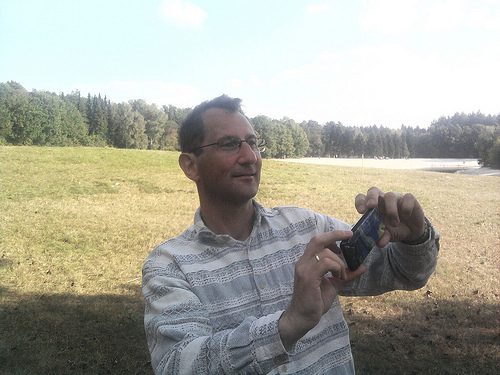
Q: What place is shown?
A: It is a field.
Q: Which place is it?
A: It is a field.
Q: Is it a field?
A: Yes, it is a field.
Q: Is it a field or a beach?
A: It is a field.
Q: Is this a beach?
A: No, it is a field.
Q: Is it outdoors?
A: Yes, it is outdoors.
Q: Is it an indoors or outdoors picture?
A: It is outdoors.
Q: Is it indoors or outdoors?
A: It is outdoors.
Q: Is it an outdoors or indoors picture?
A: It is outdoors.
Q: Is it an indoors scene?
A: No, it is outdoors.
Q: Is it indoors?
A: No, it is outdoors.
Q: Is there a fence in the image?
A: No, there are no fences.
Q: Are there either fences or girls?
A: No, there are no fences or girls.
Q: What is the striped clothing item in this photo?
A: The clothing item is a shirt.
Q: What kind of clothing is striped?
A: The clothing is a shirt.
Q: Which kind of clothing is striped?
A: The clothing is a shirt.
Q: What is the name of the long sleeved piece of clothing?
A: The clothing item is a shirt.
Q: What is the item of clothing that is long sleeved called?
A: The clothing item is a shirt.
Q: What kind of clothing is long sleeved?
A: The clothing is a shirt.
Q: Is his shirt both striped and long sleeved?
A: Yes, the shirt is striped and long sleeved.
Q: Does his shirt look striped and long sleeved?
A: Yes, the shirt is striped and long sleeved.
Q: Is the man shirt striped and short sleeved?
A: No, the shirt is striped but long sleeved.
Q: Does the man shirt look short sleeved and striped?
A: No, the shirt is striped but long sleeved.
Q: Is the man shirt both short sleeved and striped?
A: No, the shirt is striped but long sleeved.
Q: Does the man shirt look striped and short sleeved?
A: No, the shirt is striped but long sleeved.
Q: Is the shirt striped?
A: Yes, the shirt is striped.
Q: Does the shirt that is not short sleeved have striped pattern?
A: Yes, the shirt is striped.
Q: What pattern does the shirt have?
A: The shirt has striped pattern.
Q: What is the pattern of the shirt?
A: The shirt is striped.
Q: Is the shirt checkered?
A: No, the shirt is striped.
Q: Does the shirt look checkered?
A: No, the shirt is striped.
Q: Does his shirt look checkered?
A: No, the shirt is striped.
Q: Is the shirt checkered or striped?
A: The shirt is striped.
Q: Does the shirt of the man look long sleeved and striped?
A: Yes, the shirt is long sleeved and striped.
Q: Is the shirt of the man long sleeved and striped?
A: Yes, the shirt is long sleeved and striped.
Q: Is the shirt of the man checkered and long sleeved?
A: No, the shirt is long sleeved but striped.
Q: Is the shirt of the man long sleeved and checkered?
A: No, the shirt is long sleeved but striped.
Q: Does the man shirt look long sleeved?
A: Yes, the shirt is long sleeved.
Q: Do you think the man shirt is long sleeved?
A: Yes, the shirt is long sleeved.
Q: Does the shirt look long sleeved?
A: Yes, the shirt is long sleeved.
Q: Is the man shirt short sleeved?
A: No, the shirt is long sleeved.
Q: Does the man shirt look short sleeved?
A: No, the shirt is long sleeved.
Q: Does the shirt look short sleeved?
A: No, the shirt is long sleeved.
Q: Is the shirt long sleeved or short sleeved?
A: The shirt is long sleeved.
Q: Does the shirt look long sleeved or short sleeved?
A: The shirt is long sleeved.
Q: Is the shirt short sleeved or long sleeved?
A: The shirt is long sleeved.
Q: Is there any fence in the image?
A: No, there are no fences.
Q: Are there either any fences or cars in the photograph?
A: No, there are no fences or cars.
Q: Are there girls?
A: No, there are no girls.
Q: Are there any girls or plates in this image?
A: No, there are no girls or plates.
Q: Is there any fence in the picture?
A: No, there are no fences.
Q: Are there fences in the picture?
A: No, there are no fences.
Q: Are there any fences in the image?
A: No, there are no fences.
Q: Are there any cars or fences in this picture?
A: No, there are no fences or cars.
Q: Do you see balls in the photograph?
A: No, there are no balls.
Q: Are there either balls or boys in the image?
A: No, there are no balls or boys.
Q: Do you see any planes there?
A: No, there are no planes.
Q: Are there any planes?
A: No, there are no planes.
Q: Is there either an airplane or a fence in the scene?
A: No, there are no airplanes or fences.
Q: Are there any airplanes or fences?
A: No, there are no airplanes or fences.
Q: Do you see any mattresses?
A: No, there are no mattresses.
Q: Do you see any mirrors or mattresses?
A: No, there are no mattresses or mirrors.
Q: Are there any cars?
A: No, there are no cars.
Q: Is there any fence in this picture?
A: No, there are no fences.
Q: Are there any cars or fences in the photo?
A: No, there are no cars or fences.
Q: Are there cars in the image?
A: No, there are no cars.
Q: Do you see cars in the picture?
A: No, there are no cars.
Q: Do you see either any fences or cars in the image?
A: No, there are no cars or fences.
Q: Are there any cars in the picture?
A: No, there are no cars.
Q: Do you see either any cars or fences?
A: No, there are no cars or fences.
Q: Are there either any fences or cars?
A: No, there are no cars or fences.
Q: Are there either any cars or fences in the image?
A: No, there are no cars or fences.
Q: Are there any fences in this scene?
A: No, there are no fences.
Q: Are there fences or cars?
A: No, there are no fences or cars.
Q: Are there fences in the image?
A: No, there are no fences.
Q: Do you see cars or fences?
A: No, there are no fences or cars.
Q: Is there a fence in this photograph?
A: No, there are no fences.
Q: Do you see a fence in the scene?
A: No, there are no fences.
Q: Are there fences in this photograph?
A: No, there are no fences.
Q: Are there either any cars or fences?
A: No, there are no fences or cars.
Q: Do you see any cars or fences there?
A: No, there are no fences or cars.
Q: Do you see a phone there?
A: Yes, there is a phone.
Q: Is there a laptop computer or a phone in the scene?
A: Yes, there is a phone.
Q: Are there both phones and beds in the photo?
A: No, there is a phone but no beds.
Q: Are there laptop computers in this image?
A: No, there are no laptop computers.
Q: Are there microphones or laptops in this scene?
A: No, there are no laptops or microphones.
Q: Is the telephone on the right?
A: Yes, the telephone is on the right of the image.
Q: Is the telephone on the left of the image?
A: No, the telephone is on the right of the image.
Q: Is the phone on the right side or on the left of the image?
A: The phone is on the right of the image.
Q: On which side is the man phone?
A: The telephone is on the right of the image.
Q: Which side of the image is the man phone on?
A: The telephone is on the right of the image.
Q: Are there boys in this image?
A: No, there are no boys.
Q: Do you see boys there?
A: No, there are no boys.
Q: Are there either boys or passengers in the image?
A: No, there are no boys or passengers.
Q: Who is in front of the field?
A: The man is in front of the field.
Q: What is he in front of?
A: The man is in front of the field.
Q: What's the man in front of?
A: The man is in front of the field.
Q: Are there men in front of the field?
A: Yes, there is a man in front of the field.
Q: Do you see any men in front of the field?
A: Yes, there is a man in front of the field.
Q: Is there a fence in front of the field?
A: No, there is a man in front of the field.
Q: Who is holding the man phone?
A: The man is holding the phone.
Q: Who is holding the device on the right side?
A: The man is holding the phone.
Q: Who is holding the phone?
A: The man is holding the phone.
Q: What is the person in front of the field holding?
A: The man is holding the telephone.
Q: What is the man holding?
A: The man is holding the telephone.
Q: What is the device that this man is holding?
A: The device is a phone.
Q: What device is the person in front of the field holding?
A: The man is holding the phone.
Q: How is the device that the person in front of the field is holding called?
A: The device is a phone.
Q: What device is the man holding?
A: The man is holding the phone.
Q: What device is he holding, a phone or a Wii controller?
A: The man is holding a phone.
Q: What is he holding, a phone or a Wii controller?
A: The man is holding a phone.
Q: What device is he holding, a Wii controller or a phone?
A: The man is holding a phone.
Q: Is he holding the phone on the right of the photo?
A: Yes, the man is holding the telephone.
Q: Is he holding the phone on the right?
A: Yes, the man is holding the telephone.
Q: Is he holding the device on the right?
A: Yes, the man is holding the telephone.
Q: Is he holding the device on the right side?
A: Yes, the man is holding the telephone.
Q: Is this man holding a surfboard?
A: No, the man is holding the telephone.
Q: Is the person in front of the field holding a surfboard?
A: No, the man is holding the telephone.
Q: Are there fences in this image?
A: No, there are no fences.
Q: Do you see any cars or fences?
A: No, there are no fences or cars.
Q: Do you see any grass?
A: Yes, there is grass.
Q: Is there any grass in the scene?
A: Yes, there is grass.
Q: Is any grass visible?
A: Yes, there is grass.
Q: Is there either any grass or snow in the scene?
A: Yes, there is grass.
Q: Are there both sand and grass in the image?
A: No, there is grass but no sand.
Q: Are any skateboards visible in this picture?
A: No, there are no skateboards.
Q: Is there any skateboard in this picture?
A: No, there are no skateboards.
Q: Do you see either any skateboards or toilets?
A: No, there are no skateboards or toilets.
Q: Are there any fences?
A: No, there are no fences.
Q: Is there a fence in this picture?
A: No, there are no fences.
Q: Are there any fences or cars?
A: No, there are no fences or cars.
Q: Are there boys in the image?
A: No, there are no boys.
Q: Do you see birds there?
A: No, there are no birds.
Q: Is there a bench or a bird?
A: No, there are no birds or benches.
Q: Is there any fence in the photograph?
A: No, there are no fences.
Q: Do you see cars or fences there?
A: No, there are no fences or cars.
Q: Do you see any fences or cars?
A: No, there are no fences or cars.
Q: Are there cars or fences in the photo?
A: No, there are no fences or cars.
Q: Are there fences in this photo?
A: No, there are no fences.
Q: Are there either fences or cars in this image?
A: No, there are no fences or cars.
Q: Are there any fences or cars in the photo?
A: No, there are no fences or cars.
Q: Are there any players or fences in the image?
A: No, there are no fences or players.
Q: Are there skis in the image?
A: No, there are no skis.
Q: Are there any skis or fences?
A: No, there are no skis or fences.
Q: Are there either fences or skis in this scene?
A: No, there are no skis or fences.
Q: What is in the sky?
A: The clouds are in the sky.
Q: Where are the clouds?
A: The clouds are in the sky.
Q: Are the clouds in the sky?
A: Yes, the clouds are in the sky.